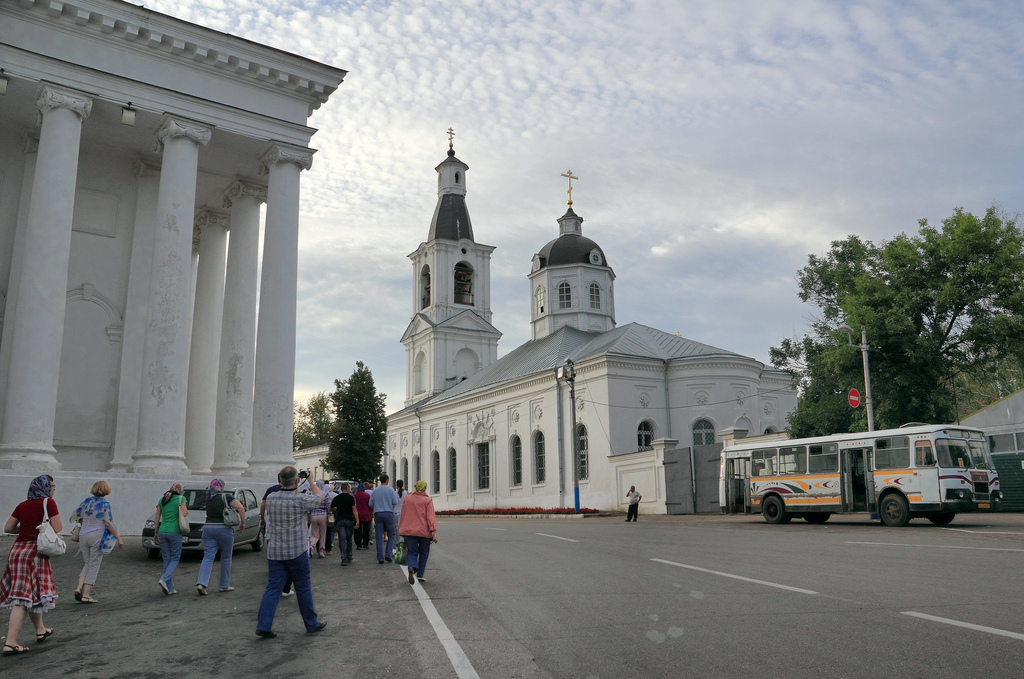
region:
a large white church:
[301, 123, 798, 517]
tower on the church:
[403, 129, 502, 404]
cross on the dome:
[561, 169, 578, 202]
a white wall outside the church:
[608, 438, 716, 512]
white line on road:
[649, 554, 806, 592]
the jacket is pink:
[394, 492, 432, 530]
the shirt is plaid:
[258, 485, 320, 561]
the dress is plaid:
[1, 542, 56, 609]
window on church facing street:
[691, 418, 718, 447]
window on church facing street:
[567, 424, 591, 480]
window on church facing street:
[527, 427, 542, 490]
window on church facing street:
[507, 431, 529, 487]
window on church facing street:
[473, 440, 493, 489]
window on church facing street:
[444, 442, 459, 489]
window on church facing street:
[428, 449, 446, 498]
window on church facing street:
[408, 449, 423, 489]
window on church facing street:
[385, 456, 398, 487]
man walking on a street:
[239, 453, 326, 647]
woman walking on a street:
[14, 459, 68, 649]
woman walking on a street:
[64, 459, 150, 621]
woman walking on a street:
[384, 459, 446, 584]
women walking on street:
[141, 472, 247, 612]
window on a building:
[516, 419, 564, 499]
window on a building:
[430, 257, 487, 312]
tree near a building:
[877, 190, 980, 340]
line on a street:
[651, 538, 857, 622]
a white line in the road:
[628, 549, 832, 617]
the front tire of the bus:
[749, 495, 800, 533]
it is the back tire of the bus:
[878, 486, 911, 528]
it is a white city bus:
[704, 413, 987, 531]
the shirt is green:
[145, 497, 199, 536]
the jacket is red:
[400, 499, 443, 532]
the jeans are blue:
[256, 557, 323, 621]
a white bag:
[37, 502, 64, 559]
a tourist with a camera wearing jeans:
[251, 464, 328, 642]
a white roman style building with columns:
[4, 2, 347, 535]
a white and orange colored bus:
[718, 424, 1006, 530]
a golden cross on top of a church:
[561, 168, 580, 204]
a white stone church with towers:
[295, 127, 802, 511]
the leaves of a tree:
[315, 360, 386, 494]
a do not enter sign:
[842, 386, 861, 406]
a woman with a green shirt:
[155, 483, 188, 597]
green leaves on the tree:
[953, 203, 988, 249]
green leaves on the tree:
[792, 332, 824, 402]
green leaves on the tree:
[813, 355, 845, 419]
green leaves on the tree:
[877, 329, 909, 384]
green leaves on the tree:
[839, 247, 903, 334]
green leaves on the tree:
[792, 209, 853, 282]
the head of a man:
[273, 467, 311, 500]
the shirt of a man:
[263, 472, 317, 568]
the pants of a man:
[234, 523, 348, 650]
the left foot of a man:
[236, 619, 285, 645]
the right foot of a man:
[311, 612, 334, 633]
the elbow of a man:
[320, 492, 333, 505]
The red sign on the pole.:
[840, 376, 863, 414]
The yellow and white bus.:
[710, 415, 1011, 520]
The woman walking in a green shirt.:
[137, 469, 179, 584]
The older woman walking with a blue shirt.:
[64, 469, 107, 605]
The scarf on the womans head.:
[23, 465, 53, 500]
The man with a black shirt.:
[326, 472, 352, 559]